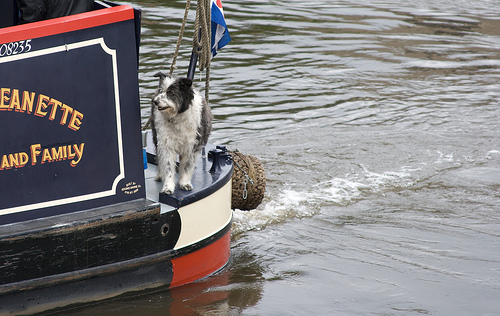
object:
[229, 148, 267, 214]
basket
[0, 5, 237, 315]
front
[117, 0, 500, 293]
ripples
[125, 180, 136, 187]
small writing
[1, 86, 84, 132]
yellow writing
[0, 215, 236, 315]
bottom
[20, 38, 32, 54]
white numbers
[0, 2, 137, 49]
red trim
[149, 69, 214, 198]
bubbley wake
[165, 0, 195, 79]
brown ropes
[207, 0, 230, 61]
flag area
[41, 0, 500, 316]
water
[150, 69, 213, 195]
dog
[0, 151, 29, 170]
words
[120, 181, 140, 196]
logo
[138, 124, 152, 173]
tire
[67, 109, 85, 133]
letters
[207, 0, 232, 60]
flag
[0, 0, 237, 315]
boat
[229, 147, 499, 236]
wave